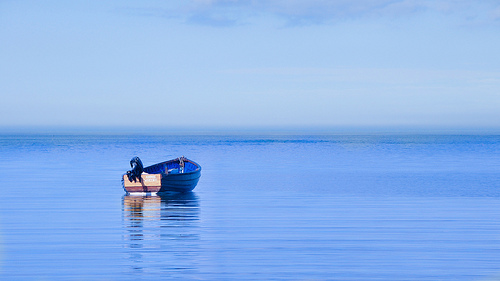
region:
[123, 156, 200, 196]
A boat on the water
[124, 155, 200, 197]
A small boat beneath the sky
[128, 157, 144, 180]
An engine on the boat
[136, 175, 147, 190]
A shadow on the boat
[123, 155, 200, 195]
The boat is empty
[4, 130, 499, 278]
A body of water beneath the boat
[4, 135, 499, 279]
The water is calm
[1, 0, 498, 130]
A clear sky above the boat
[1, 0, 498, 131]
The sky above the water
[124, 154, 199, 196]
The boat is on the water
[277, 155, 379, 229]
Water in the ocean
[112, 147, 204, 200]
Boat in the waters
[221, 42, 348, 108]
White clouds in the photo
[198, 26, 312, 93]
Cloudy skies in the photo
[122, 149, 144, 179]
Engine of a boat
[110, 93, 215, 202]
A motor boat in the waters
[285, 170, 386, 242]
Sea waters in the photo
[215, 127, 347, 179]
Calm sea waters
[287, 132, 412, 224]
Waters of the sea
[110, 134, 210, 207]
A boat in the ocean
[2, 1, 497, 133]
The sky is hazy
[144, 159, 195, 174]
Boat has blue interior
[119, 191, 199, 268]
Reflection of the boat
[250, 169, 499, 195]
Dark patch of water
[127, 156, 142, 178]
Engine on the boat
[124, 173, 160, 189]
Back of boat is brown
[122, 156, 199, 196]
Nobody is in the boat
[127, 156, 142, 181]
The engine is black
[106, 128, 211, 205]
Blue boat on the ocean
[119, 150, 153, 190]
engine on a boat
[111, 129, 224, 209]
boat in the water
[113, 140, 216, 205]
blue boat on the river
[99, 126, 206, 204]
boat on top of the ocean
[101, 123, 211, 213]
boat in the ocean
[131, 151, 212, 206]
boat in the ocean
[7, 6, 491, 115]
The sky is clear blue.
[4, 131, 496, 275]
The water is blue.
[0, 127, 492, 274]
The water is calm.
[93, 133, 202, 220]
The boat is on the water.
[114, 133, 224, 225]
The boat is blue.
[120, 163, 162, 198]
The back of the boat is tan.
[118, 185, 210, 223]
The relfection of the boat.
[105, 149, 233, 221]
The boat is empty.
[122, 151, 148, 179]
The motor is black.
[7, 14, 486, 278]
The sun is shining on the boat.